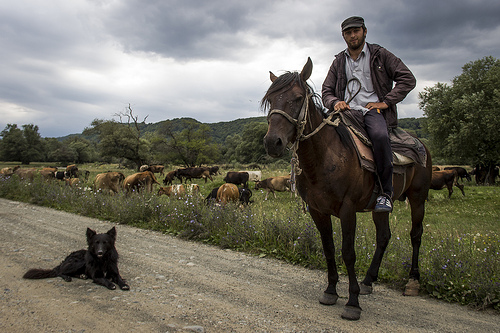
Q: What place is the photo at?
A: It is at the road.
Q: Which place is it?
A: It is a road.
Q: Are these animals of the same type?
A: No, they are horses and dogs.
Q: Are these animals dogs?
A: No, they are horses and dogs.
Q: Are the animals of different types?
A: Yes, they are horses and dogs.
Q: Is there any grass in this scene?
A: Yes, there is grass.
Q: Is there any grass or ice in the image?
A: Yes, there is grass.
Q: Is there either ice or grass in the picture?
A: Yes, there is grass.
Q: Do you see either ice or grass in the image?
A: Yes, there is grass.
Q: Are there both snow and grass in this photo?
A: No, there is grass but no snow.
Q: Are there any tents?
A: No, there are no tents.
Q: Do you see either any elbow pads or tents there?
A: No, there are no tents or elbow pads.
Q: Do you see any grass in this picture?
A: Yes, there is grass.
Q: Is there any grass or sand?
A: Yes, there is grass.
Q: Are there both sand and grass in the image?
A: No, there is grass but no sand.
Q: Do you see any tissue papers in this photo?
A: No, there are no tissue papers.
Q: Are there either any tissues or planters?
A: No, there are no tissues or planters.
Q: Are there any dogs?
A: Yes, there is a dog.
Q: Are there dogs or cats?
A: Yes, there is a dog.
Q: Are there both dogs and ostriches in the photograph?
A: No, there is a dog but no ostriches.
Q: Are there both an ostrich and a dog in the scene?
A: No, there is a dog but no ostriches.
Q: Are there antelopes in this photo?
A: No, there are no antelopes.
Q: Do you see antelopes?
A: No, there are no antelopes.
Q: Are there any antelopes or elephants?
A: No, there are no antelopes or elephants.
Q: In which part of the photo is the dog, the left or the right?
A: The dog is on the left of the image.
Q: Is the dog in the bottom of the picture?
A: Yes, the dog is in the bottom of the image.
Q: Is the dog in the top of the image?
A: No, the dog is in the bottom of the image.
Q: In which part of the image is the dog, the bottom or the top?
A: The dog is in the bottom of the image.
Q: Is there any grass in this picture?
A: Yes, there is grass.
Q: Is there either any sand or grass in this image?
A: Yes, there is grass.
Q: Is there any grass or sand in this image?
A: Yes, there is grass.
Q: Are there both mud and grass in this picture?
A: No, there is grass but no mud.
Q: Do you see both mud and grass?
A: No, there is grass but no mud.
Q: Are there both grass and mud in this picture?
A: No, there is grass but no mud.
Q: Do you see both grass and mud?
A: No, there is grass but no mud.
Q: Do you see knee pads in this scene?
A: No, there are no knee pads.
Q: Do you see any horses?
A: Yes, there is a horse.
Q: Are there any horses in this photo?
A: Yes, there is a horse.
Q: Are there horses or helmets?
A: Yes, there is a horse.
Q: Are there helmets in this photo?
A: No, there are no helmets.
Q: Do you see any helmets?
A: No, there are no helmets.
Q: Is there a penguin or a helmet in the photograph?
A: No, there are no helmets or penguins.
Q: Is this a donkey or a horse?
A: This is a horse.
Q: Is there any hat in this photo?
A: Yes, there is a hat.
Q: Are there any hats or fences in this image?
A: Yes, there is a hat.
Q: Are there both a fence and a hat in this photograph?
A: No, there is a hat but no fences.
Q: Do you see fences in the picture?
A: No, there are no fences.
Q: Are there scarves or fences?
A: No, there are no fences or scarves.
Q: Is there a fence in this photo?
A: No, there are no fences.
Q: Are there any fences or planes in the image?
A: No, there are no fences or planes.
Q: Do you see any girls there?
A: No, there are no girls.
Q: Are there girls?
A: No, there are no girls.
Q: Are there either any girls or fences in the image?
A: No, there are no girls or fences.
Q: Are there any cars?
A: No, there are no cars.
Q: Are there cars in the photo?
A: No, there are no cars.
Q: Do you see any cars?
A: No, there are no cars.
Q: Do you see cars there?
A: No, there are no cars.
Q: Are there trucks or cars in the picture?
A: No, there are no cars or trucks.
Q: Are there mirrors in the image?
A: No, there are no mirrors.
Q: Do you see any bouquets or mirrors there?
A: No, there are no mirrors or bouquets.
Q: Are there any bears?
A: No, there are no bears.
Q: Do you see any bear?
A: No, there are no bears.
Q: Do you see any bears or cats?
A: No, there are no bears or cats.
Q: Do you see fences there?
A: No, there are no fences.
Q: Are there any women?
A: No, there are no women.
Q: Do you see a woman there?
A: No, there are no women.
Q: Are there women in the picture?
A: No, there are no women.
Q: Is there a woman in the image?
A: No, there are no women.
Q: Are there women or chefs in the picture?
A: No, there are no women or chefs.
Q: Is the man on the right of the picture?
A: Yes, the man is on the right of the image.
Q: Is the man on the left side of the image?
A: No, the man is on the right of the image.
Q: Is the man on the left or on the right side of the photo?
A: The man is on the right of the image.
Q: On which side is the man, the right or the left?
A: The man is on the right of the image.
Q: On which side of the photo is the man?
A: The man is on the right of the image.